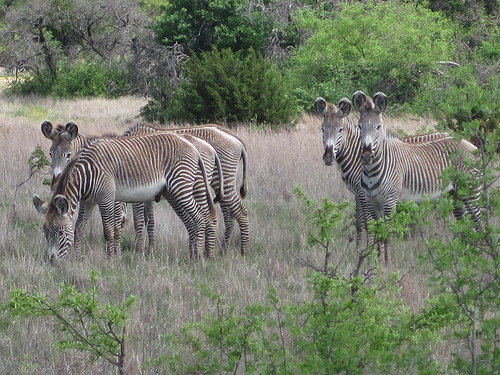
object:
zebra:
[348, 90, 488, 265]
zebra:
[315, 97, 450, 251]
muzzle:
[322, 146, 337, 167]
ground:
[0, 67, 499, 374]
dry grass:
[0, 68, 499, 374]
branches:
[86, 13, 107, 46]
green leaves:
[187, 4, 201, 15]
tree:
[143, 0, 273, 61]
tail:
[239, 148, 249, 199]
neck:
[358, 137, 389, 172]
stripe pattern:
[360, 144, 389, 191]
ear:
[51, 193, 69, 215]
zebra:
[41, 118, 226, 261]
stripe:
[166, 173, 194, 184]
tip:
[239, 183, 248, 199]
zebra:
[114, 122, 251, 255]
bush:
[0, 269, 137, 374]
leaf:
[304, 280, 312, 291]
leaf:
[330, 283, 336, 291]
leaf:
[364, 316, 376, 327]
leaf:
[330, 346, 338, 354]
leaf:
[366, 220, 383, 230]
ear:
[30, 192, 51, 215]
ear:
[373, 90, 387, 114]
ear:
[352, 90, 368, 111]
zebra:
[33, 130, 217, 265]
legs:
[166, 174, 207, 257]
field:
[0, 67, 500, 374]